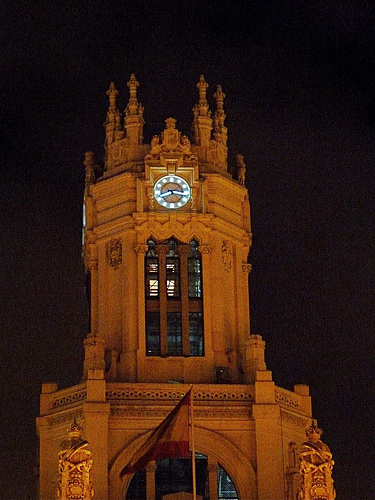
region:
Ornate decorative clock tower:
[78, 68, 261, 380]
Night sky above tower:
[3, 188, 46, 229]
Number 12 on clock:
[168, 176, 176, 182]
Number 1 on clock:
[176, 177, 184, 184]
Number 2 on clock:
[180, 184, 190, 189]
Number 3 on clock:
[182, 190, 190, 195]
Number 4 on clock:
[179, 196, 189, 203]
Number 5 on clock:
[178, 199, 187, 207]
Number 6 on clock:
[172, 201, 181, 210]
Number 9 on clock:
[155, 192, 162, 196]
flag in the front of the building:
[113, 385, 208, 498]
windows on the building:
[139, 241, 204, 358]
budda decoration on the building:
[289, 416, 333, 497]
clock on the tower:
[154, 163, 193, 213]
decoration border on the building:
[128, 387, 166, 399]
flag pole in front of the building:
[184, 382, 198, 499]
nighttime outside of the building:
[307, 305, 354, 356]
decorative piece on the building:
[103, 232, 124, 278]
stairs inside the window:
[216, 464, 236, 498]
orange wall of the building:
[137, 359, 216, 379]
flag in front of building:
[100, 385, 209, 492]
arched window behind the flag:
[120, 424, 252, 498]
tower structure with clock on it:
[45, 65, 294, 485]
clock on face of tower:
[150, 170, 189, 206]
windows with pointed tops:
[147, 233, 206, 358]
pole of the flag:
[184, 396, 200, 497]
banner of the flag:
[107, 389, 195, 469]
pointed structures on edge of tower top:
[82, 68, 253, 176]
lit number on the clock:
[161, 177, 165, 182]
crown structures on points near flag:
[59, 419, 325, 444]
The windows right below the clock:
[144, 238, 202, 355]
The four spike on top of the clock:
[102, 69, 225, 127]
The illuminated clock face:
[158, 176, 189, 212]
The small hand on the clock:
[171, 192, 190, 197]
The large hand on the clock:
[150, 189, 173, 204]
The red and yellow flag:
[130, 391, 190, 471]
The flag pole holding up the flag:
[184, 389, 204, 496]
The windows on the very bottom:
[122, 441, 230, 498]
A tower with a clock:
[48, 81, 338, 498]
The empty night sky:
[272, 58, 372, 322]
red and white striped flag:
[114, 383, 192, 482]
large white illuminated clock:
[148, 173, 191, 209]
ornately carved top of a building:
[74, 70, 251, 183]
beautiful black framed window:
[136, 228, 209, 359]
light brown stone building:
[34, 68, 338, 499]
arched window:
[110, 420, 255, 498]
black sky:
[1, 1, 373, 497]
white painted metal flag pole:
[184, 380, 200, 497]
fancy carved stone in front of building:
[283, 417, 334, 498]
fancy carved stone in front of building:
[48, 419, 96, 498]